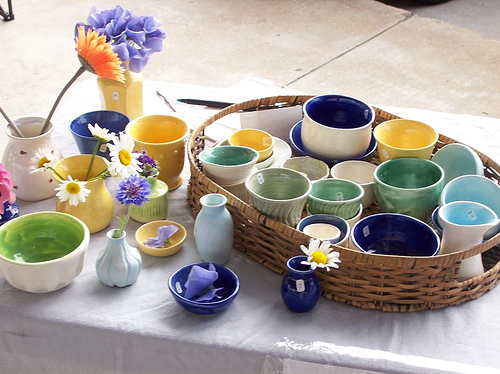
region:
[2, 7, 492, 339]
An assortment of different size containers.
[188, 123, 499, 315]
A wicker basket holding containers.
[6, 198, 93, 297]
A round white bowl that's green inside.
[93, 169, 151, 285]
A small vase with blue flower.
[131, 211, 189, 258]
Small round yellow container.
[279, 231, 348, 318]
Daisy in a blue container.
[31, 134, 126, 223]
Four daisies in yellow container.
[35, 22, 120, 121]
A long stemmed orange flower.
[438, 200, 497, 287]
White container that's blue inside.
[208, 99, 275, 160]
Small yellow container in basket.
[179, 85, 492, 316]
wicker basket holding a variety of cups and vases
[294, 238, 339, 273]
white daisy with yellow center in a dark blue vase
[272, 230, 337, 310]
small dark blue vase on the outside of the wicker basket with a dainty white and yellow daisy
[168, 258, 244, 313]
round dark blue bowl on the white table cloth at the edge of the table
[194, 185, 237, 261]
slender, light blue vase on the outside of wicker basket but touching the side of it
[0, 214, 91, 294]
white bowl on white table cloth with green on the inside of bowl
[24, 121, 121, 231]
yellow vase beside white bowl holding 4 daisies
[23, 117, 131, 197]
four daisies inside of yellow vase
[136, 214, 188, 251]
small yellow bowl on table cloth with pastel purple petal inside of it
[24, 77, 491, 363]
table with white table cloth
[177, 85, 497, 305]
a wicker basket on the table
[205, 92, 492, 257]
ceramics in the basket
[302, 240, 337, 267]
a daisey in the blue vase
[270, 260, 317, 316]
the vase on the table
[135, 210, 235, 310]
flowers in the bowls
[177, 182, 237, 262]
a white vase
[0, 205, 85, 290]
the bowl is green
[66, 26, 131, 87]
the sunflower in the vase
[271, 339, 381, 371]
plastic on the table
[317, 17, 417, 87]
crack in the sidewalk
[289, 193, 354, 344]
the flower is white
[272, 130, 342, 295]
the flower is white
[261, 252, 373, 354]
the flower is white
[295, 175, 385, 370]
the flower is white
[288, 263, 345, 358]
the flower is white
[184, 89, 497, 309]
The basket is holding vases.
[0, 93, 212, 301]
Several vases and bowls are on the table.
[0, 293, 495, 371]
The tablecloth is white.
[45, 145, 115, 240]
The vase is yellow.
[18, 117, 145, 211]
The vase holds daisies.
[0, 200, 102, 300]
The bowl is white.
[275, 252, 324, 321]
The vase is blue.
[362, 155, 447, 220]
The vase is green.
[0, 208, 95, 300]
The bowl is empty.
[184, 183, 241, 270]
The vase is light blue.